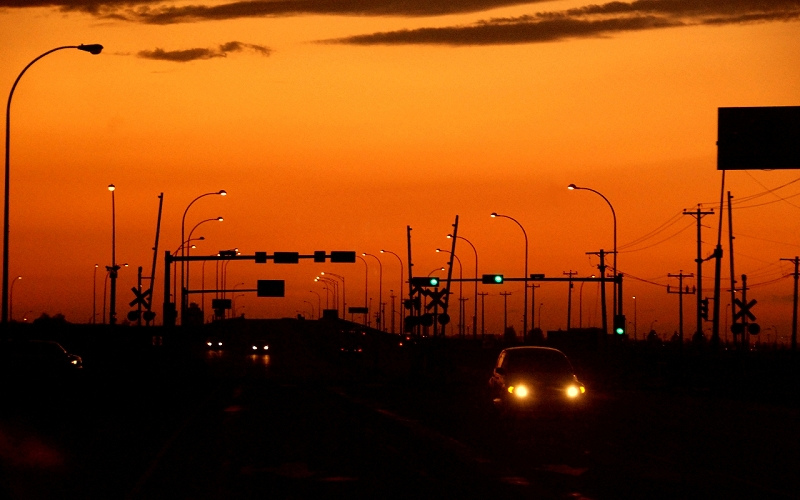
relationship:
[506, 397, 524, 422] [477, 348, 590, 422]
tire on vehicle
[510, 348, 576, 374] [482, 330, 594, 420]
windshield on vehicle